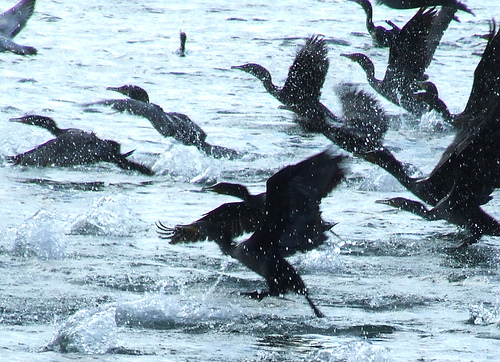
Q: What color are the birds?
A: Black.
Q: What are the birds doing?
A: Flying.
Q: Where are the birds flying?
A: Over the water.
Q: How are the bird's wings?
A: Outstretched.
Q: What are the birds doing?
A: Flying.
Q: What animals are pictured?
A: Birds.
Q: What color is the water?
A: Blue.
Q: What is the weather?
A: Rainy.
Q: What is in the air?
A: Raindrops.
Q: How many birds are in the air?
A: Ten.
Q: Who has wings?
A: Birds.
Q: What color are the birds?
A: Black.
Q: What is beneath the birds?
A: Water.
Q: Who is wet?
A: The birds.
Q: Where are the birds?
A: In the water.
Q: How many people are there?
A: None.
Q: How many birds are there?
A: More than three.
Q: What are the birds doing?
A: Flying.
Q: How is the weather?
A: Rainy.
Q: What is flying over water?
A: Birds with wings spread.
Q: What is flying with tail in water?
A: Black water bird.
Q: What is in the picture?
A: Flock of black sea birds.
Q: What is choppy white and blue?
A: Water.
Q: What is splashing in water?
A: Black birds.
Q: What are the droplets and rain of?
A: Water.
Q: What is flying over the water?
A: Black birds with large wings expanded.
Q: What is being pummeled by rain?
A: Blue water.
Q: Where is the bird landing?
A: In the water.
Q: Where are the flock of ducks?
A: Playing in a river.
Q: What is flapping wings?
A: Duck.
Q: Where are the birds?
A: On the water.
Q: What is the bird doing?
A: Flapping wings.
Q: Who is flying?
A: The birds.